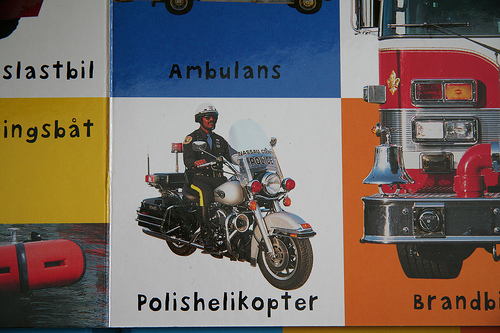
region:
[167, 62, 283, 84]
the word Ambulans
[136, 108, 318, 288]
a police riding a motorcycle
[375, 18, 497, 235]
part of a fire truck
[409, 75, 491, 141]
the headlights of the fire truck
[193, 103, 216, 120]
a white helmet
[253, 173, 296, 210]
the headlights o f the motorcycle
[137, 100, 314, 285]
a police on the motorcycle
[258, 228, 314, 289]
the frontwheel of the motorcycle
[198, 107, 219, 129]
the head of the police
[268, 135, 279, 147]
the rearview mirror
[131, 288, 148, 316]
The letter is black.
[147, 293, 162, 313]
The letter is black.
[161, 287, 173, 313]
The letter is black.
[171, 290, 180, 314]
The letter is black.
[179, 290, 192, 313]
The letter is black.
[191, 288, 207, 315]
The letter is black.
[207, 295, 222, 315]
The letter is black.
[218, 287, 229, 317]
The letter is black.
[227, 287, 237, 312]
The letter is black.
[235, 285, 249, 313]
The letter is black.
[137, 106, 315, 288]
a police officer on a motorcycle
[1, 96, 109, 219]
yellow square with black writing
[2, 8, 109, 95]
white square with black writing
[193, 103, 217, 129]
white and black safety helmet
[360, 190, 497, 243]
chrome bumper on the truck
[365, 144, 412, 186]
chrome bell on the fire truck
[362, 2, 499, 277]
a red fire truck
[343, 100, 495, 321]
orange square with black writing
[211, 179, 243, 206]
white gas tank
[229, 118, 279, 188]
clear windshield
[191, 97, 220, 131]
police black and white helmet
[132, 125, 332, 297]
police motorcycle in black and white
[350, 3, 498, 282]
red and white firefighter truck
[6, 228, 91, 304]
sea tube in water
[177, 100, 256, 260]
police officer in uniform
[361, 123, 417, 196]
chrome bell on fire truck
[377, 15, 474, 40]
black window wiper on window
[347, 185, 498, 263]
chrome bumper on fire truck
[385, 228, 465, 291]
tire on truck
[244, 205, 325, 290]
front tire of motorcycle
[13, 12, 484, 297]
an old advetisement photo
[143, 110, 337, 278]
a police officer in the picture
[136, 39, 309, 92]
this word can be translated to "abulance"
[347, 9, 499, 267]
a fire truck in the picture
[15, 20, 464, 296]
this is a picture about emergency services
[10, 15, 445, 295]
this picture is about emergency responders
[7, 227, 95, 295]
a red board in the photo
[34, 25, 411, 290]
the picture has colored checkered squares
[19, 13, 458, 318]
this picture is old